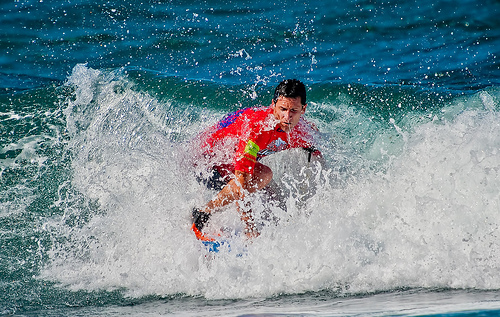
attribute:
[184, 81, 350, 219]
man — surfing, riding board, white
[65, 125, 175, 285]
water — clear, flat, big, blue, shiny, splashing, green, shallow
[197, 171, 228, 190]
shorts — black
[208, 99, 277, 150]
shirt — red, short, yellow, blue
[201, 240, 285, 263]
board — black